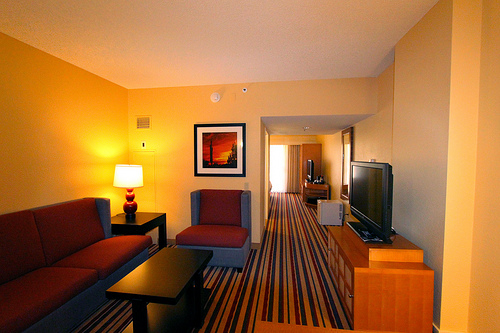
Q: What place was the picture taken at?
A: It was taken at the hotel room.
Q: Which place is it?
A: It is a hotel room.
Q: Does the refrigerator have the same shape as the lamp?
A: No, the lamp is round and the refrigerator is square.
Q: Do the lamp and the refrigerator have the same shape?
A: No, the lamp is round and the refrigerator is square.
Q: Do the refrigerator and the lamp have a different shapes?
A: Yes, the refrigerator is round and the lamp is square.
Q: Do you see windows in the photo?
A: Yes, there is a window.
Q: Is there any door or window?
A: Yes, there is a window.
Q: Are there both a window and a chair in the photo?
A: Yes, there are both a window and a chair.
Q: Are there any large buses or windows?
A: Yes, there is a large window.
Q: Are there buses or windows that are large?
A: Yes, the window is large.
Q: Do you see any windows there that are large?
A: Yes, there is a large window.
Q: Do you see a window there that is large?
A: Yes, there is a window that is large.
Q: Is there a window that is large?
A: Yes, there is a window that is large.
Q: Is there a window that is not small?
A: Yes, there is a large window.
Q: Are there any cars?
A: No, there are no cars.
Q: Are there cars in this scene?
A: No, there are no cars.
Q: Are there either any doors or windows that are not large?
A: No, there is a window but it is large.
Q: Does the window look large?
A: Yes, the window is large.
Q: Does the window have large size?
A: Yes, the window is large.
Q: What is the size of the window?
A: The window is large.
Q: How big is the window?
A: The window is large.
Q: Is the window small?
A: No, the window is large.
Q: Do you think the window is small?
A: No, the window is large.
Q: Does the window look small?
A: No, the window is large.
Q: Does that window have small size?
A: No, the window is large.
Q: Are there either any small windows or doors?
A: No, there is a window but it is large.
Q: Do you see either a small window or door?
A: No, there is a window but it is large.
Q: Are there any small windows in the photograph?
A: No, there is a window but it is large.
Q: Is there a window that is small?
A: No, there is a window but it is large.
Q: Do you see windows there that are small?
A: No, there is a window but it is large.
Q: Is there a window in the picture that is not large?
A: No, there is a window but it is large.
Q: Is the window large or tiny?
A: The window is large.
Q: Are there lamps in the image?
A: Yes, there is a lamp.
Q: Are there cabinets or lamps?
A: Yes, there is a lamp.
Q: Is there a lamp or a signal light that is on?
A: Yes, the lamp is on.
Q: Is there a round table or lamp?
A: Yes, there is a round lamp.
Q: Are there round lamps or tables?
A: Yes, there is a round lamp.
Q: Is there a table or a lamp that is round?
A: Yes, the lamp is round.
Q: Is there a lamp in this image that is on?
A: Yes, there is a lamp that is on.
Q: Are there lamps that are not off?
A: Yes, there is a lamp that is on.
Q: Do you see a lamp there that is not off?
A: Yes, there is a lamp that is on .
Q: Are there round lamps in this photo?
A: Yes, there is a round lamp.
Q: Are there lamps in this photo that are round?
A: Yes, there is a lamp that is round.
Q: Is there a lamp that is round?
A: Yes, there is a lamp that is round.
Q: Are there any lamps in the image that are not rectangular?
A: Yes, there is a round lamp.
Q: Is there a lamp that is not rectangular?
A: Yes, there is a round lamp.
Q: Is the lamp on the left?
A: Yes, the lamp is on the left of the image.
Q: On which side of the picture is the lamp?
A: The lamp is on the left of the image.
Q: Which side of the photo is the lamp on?
A: The lamp is on the left of the image.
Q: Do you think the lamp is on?
A: Yes, the lamp is on.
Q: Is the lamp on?
A: Yes, the lamp is on.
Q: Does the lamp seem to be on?
A: Yes, the lamp is on.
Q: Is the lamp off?
A: No, the lamp is on.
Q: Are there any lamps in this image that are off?
A: No, there is a lamp but it is on.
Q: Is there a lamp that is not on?
A: No, there is a lamp but it is on.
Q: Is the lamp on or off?
A: The lamp is on.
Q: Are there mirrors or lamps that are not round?
A: No, there is a lamp but it is round.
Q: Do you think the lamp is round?
A: Yes, the lamp is round.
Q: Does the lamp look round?
A: Yes, the lamp is round.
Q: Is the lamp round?
A: Yes, the lamp is round.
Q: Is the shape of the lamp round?
A: Yes, the lamp is round.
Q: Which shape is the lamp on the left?
A: The lamp is round.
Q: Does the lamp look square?
A: No, the lamp is round.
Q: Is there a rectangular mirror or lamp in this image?
A: No, there is a lamp but it is round.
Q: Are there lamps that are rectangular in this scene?
A: No, there is a lamp but it is round.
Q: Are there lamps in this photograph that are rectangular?
A: No, there is a lamp but it is round.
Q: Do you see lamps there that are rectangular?
A: No, there is a lamp but it is round.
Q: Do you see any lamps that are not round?
A: No, there is a lamp but it is round.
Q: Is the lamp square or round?
A: The lamp is round.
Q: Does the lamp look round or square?
A: The lamp is round.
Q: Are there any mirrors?
A: No, there are no mirrors.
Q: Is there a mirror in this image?
A: No, there are no mirrors.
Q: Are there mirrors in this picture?
A: No, there are no mirrors.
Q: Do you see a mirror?
A: No, there are no mirrors.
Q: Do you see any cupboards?
A: No, there are no cupboards.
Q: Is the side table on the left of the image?
A: Yes, the side table is on the left of the image.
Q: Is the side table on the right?
A: No, the side table is on the left of the image.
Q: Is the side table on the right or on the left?
A: The side table is on the left of the image.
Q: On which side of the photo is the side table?
A: The side table is on the left of the image.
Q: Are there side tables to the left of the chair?
A: Yes, there is a side table to the left of the chair.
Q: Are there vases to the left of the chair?
A: No, there is a side table to the left of the chair.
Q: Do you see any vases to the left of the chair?
A: No, there is a side table to the left of the chair.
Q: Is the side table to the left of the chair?
A: Yes, the side table is to the left of the chair.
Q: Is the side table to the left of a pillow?
A: No, the side table is to the left of the chair.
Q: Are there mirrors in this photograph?
A: No, there are no mirrors.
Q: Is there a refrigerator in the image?
A: Yes, there is a refrigerator.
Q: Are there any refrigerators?
A: Yes, there is a refrigerator.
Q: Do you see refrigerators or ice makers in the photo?
A: Yes, there is a refrigerator.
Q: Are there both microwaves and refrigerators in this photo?
A: No, there is a refrigerator but no microwaves.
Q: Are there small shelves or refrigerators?
A: Yes, there is a small refrigerator.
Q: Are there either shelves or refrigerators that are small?
A: Yes, the refrigerator is small.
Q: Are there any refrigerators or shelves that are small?
A: Yes, the refrigerator is small.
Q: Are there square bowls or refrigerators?
A: Yes, there is a square refrigerator.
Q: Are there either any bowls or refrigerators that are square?
A: Yes, the refrigerator is square.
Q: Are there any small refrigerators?
A: Yes, there is a small refrigerator.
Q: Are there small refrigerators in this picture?
A: Yes, there is a small refrigerator.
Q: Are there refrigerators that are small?
A: Yes, there is a refrigerator that is small.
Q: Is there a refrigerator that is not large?
A: Yes, there is a small refrigerator.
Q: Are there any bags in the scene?
A: No, there are no bags.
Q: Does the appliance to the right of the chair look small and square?
A: Yes, the fridge is small and square.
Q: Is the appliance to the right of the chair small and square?
A: Yes, the fridge is small and square.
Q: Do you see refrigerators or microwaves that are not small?
A: No, there is a refrigerator but it is small.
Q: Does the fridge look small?
A: Yes, the fridge is small.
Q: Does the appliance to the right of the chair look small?
A: Yes, the fridge is small.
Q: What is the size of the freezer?
A: The freezer is small.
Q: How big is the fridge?
A: The fridge is small.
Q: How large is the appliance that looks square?
A: The fridge is small.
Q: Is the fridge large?
A: No, the fridge is small.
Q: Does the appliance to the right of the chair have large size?
A: No, the refrigerator is small.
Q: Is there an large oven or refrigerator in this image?
A: No, there is a refrigerator but it is small.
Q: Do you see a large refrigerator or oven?
A: No, there is a refrigerator but it is small.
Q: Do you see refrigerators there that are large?
A: No, there is a refrigerator but it is small.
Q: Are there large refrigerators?
A: No, there is a refrigerator but it is small.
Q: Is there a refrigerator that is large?
A: No, there is a refrigerator but it is small.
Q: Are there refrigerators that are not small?
A: No, there is a refrigerator but it is small.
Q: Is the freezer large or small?
A: The freezer is small.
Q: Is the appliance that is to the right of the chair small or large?
A: The freezer is small.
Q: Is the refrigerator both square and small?
A: Yes, the refrigerator is square and small.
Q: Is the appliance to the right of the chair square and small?
A: Yes, the refrigerator is square and small.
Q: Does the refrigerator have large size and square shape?
A: No, the refrigerator is square but small.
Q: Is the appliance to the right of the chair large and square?
A: No, the refrigerator is square but small.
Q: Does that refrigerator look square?
A: Yes, the refrigerator is square.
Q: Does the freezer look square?
A: Yes, the freezer is square.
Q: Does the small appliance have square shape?
A: Yes, the freezer is square.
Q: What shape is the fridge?
A: The fridge is square.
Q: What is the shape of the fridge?
A: The fridge is square.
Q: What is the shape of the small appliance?
A: The fridge is square.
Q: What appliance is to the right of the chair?
A: The appliance is a refrigerator.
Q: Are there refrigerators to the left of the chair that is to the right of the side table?
A: No, the refrigerator is to the right of the chair.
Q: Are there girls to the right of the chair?
A: No, there is a refrigerator to the right of the chair.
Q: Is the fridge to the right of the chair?
A: Yes, the fridge is to the right of the chair.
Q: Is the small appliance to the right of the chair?
A: Yes, the fridge is to the right of the chair.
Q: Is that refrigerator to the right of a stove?
A: No, the refrigerator is to the right of the chair.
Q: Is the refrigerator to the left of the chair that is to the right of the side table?
A: No, the refrigerator is to the right of the chair.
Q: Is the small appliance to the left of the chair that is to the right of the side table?
A: No, the refrigerator is to the right of the chair.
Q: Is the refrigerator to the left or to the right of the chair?
A: The refrigerator is to the right of the chair.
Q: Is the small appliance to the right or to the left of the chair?
A: The refrigerator is to the right of the chair.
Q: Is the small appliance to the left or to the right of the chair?
A: The refrigerator is to the right of the chair.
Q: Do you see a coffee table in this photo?
A: Yes, there is a coffee table.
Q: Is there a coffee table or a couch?
A: Yes, there is a coffee table.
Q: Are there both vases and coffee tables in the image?
A: No, there is a coffee table but no vases.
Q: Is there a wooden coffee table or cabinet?
A: Yes, there is a wood coffee table.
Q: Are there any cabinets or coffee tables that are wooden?
A: Yes, the coffee table is wooden.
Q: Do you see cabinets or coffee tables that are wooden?
A: Yes, the coffee table is wooden.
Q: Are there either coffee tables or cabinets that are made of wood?
A: Yes, the coffee table is made of wood.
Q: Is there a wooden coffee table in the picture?
A: Yes, there is a wood coffee table.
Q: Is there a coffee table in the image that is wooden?
A: Yes, there is a coffee table that is wooden.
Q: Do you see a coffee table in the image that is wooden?
A: Yes, there is a coffee table that is wooden.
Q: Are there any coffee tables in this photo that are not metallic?
A: Yes, there is a wooden coffee table.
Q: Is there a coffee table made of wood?
A: Yes, there is a coffee table that is made of wood.